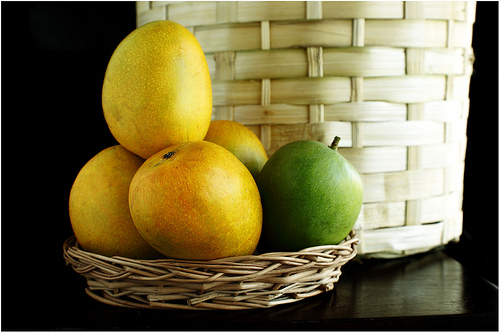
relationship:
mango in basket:
[127, 139, 264, 262] [62, 231, 360, 311]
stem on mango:
[330, 134, 342, 151] [259, 136, 365, 251]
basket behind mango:
[134, 3, 477, 258] [127, 139, 264, 262]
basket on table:
[62, 231, 360, 311] [4, 219, 497, 326]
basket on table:
[134, 3, 477, 258] [4, 219, 497, 326]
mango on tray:
[127, 139, 264, 262] [62, 231, 360, 311]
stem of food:
[330, 134, 342, 151] [259, 136, 365, 251]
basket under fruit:
[62, 231, 360, 311] [67, 142, 151, 260]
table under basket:
[4, 219, 497, 326] [62, 231, 360, 311]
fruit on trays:
[67, 142, 151, 260] [62, 231, 360, 311]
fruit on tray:
[259, 136, 365, 251] [62, 231, 360, 311]